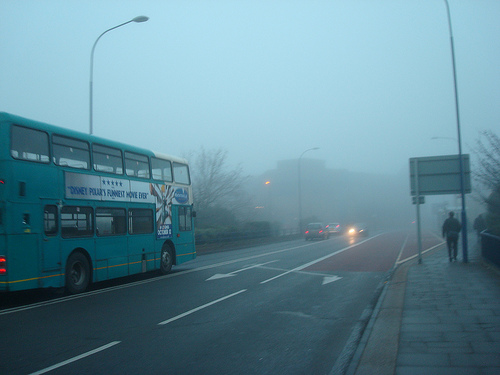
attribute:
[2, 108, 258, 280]
blue bus — double decker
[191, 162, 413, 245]
building — blue, white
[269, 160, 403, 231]
building — white, blue